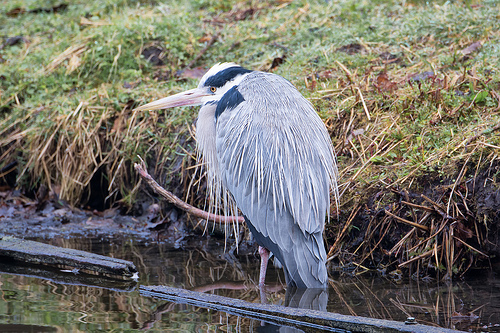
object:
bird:
[129, 61, 340, 288]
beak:
[130, 88, 203, 113]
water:
[0, 240, 499, 332]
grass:
[0, 30, 121, 148]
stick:
[138, 285, 463, 332]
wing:
[213, 71, 340, 289]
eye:
[210, 87, 216, 93]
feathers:
[184, 105, 239, 254]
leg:
[258, 245, 270, 287]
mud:
[0, 191, 190, 239]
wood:
[0, 234, 139, 282]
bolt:
[405, 317, 418, 324]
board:
[251, 286, 329, 332]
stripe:
[197, 61, 254, 87]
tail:
[274, 232, 329, 288]